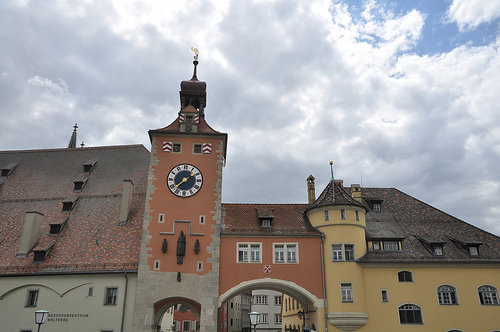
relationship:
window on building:
[397, 302, 426, 324] [305, 170, 497, 330]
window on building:
[286, 243, 299, 261] [217, 202, 328, 293]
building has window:
[0, 52, 498, 330] [229, 239, 252, 268]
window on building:
[397, 309, 408, 324] [80, 206, 265, 298]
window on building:
[397, 309, 408, 324] [280, 155, 498, 329]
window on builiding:
[397, 309, 408, 324] [2, 42, 498, 329]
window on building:
[397, 309, 408, 324] [0, 52, 498, 330]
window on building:
[269, 238, 301, 265] [0, 52, 498, 330]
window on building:
[378, 234, 402, 252] [0, 52, 498, 330]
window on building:
[397, 309, 408, 324] [220, 202, 498, 329]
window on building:
[397, 309, 408, 324] [305, 170, 497, 330]